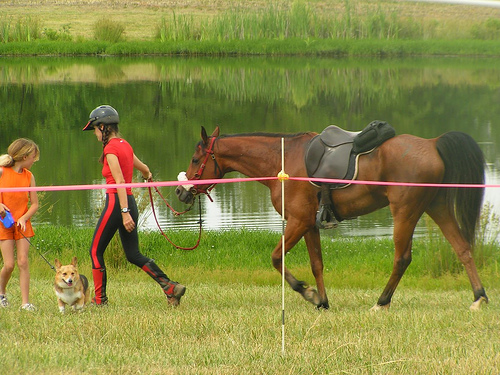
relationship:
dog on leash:
[45, 254, 85, 304] [4, 205, 82, 292]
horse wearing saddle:
[171, 111, 492, 319] [302, 122, 400, 226]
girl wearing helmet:
[4, 126, 41, 311] [83, 101, 121, 131]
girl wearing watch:
[4, 126, 41, 311] [119, 204, 134, 215]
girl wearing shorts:
[4, 126, 41, 311] [3, 205, 36, 240]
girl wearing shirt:
[4, 126, 41, 311] [99, 133, 134, 193]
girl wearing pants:
[4, 126, 41, 311] [86, 191, 187, 307]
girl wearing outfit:
[0, 126, 41, 311] [0, 161, 36, 237]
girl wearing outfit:
[78, 100, 188, 305] [86, 137, 187, 308]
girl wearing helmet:
[78, 100, 188, 305] [79, 101, 120, 130]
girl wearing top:
[78, 100, 188, 305] [104, 134, 139, 193]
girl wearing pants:
[78, 100, 188, 305] [90, 192, 171, 279]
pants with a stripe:
[90, 192, 171, 279] [85, 188, 116, 264]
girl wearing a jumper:
[78, 100, 188, 305] [1, 167, 35, 244]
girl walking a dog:
[78, 100, 188, 305] [49, 257, 89, 315]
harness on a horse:
[300, 117, 395, 194] [171, 111, 492, 319]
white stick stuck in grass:
[268, 136, 300, 353] [183, 294, 377, 371]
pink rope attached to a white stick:
[4, 174, 497, 203] [268, 136, 300, 353]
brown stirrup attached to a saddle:
[318, 191, 347, 228] [305, 120, 399, 193]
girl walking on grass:
[78, 100, 188, 305] [42, 315, 209, 372]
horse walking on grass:
[171, 111, 492, 319] [292, 315, 484, 373]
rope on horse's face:
[192, 132, 222, 186] [173, 126, 225, 204]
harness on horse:
[300, 117, 395, 194] [171, 111, 492, 319]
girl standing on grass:
[0, 126, 41, 311] [0, 319, 154, 370]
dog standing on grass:
[45, 254, 85, 304] [0, 319, 154, 370]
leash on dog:
[21, 226, 63, 269] [54, 258, 91, 316]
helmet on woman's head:
[78, 99, 122, 129] [87, 105, 124, 141]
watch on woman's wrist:
[117, 206, 139, 215] [120, 200, 132, 215]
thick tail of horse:
[439, 128, 482, 248] [171, 111, 492, 319]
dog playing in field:
[45, 254, 90, 316] [23, 314, 477, 372]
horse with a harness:
[171, 111, 492, 319] [300, 117, 395, 194]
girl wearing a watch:
[78, 100, 188, 305] [117, 206, 139, 215]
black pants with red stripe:
[92, 194, 486, 220] [90, 195, 116, 265]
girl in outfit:
[0, 126, 41, 311] [0, 161, 37, 241]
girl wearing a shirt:
[78, 100, 188, 305] [99, 133, 136, 193]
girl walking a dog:
[0, 126, 41, 311] [52, 257, 88, 317]